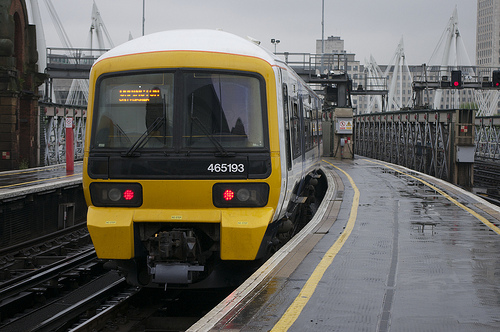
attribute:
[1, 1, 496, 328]
day — rainy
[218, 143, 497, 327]
ground — wet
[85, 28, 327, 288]
train — white, yellow, running, grey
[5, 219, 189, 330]
tracks — metal, brown, black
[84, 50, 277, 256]
front — yellow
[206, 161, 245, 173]
number — white, written, 465193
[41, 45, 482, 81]
bridge — grey, metal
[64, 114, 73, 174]
pole — red, orange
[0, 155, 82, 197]
platform — wet, concrete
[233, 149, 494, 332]
platform — wet, concrete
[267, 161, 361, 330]
stripe — yellow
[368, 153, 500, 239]
stripe — yellow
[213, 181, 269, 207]
front light — red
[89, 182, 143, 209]
front light — red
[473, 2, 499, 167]
building — bricked, grey, multystory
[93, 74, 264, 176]
window — big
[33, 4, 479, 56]
sky — grey, cloudy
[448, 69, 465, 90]
traffic light — red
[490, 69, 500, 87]
traffic light — red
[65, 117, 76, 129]
sign — white